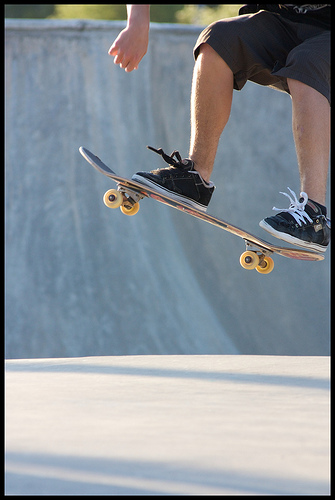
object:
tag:
[313, 223, 323, 232]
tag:
[307, 196, 319, 213]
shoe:
[258, 186, 332, 254]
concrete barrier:
[0, 14, 335, 360]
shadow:
[4, 358, 330, 390]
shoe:
[131, 145, 217, 214]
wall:
[2, 18, 335, 357]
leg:
[285, 24, 333, 209]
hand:
[107, 26, 149, 74]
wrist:
[125, 15, 153, 33]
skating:
[76, 0, 332, 276]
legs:
[188, 8, 268, 181]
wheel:
[120, 196, 139, 216]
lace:
[272, 186, 314, 228]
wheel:
[239, 250, 259, 270]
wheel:
[102, 188, 124, 209]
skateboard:
[78, 142, 325, 275]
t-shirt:
[238, 0, 333, 17]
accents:
[146, 190, 235, 233]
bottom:
[258, 219, 330, 254]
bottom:
[130, 172, 208, 213]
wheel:
[255, 255, 274, 274]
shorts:
[191, 8, 335, 107]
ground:
[2, 353, 334, 500]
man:
[108, 0, 335, 255]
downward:
[118, 23, 238, 355]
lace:
[145, 144, 191, 181]